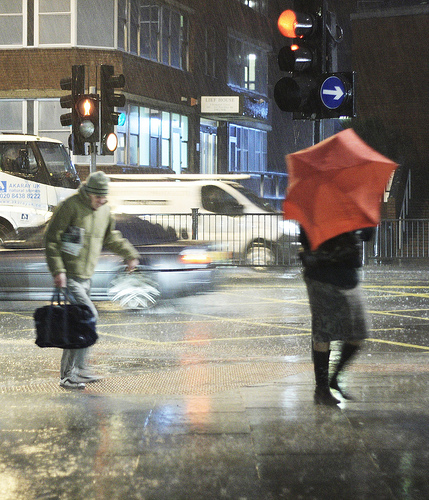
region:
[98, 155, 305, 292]
white van parked in parking lot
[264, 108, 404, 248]
red umbrella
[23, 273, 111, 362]
black canvas breif case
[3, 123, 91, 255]
cab of white truck with blue words on side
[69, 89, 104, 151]
corss walk signal light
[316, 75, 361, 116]
blue and white directional light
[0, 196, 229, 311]
black car driving down street in rain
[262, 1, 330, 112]
signal light on red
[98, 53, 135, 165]
city signal light on green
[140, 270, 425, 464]
rain on city street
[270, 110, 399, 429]
woman with red umbrella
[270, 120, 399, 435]
woman wearing black boots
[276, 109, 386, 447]
woman walking in rain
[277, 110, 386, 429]
woman wearing skirt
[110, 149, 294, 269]
white van driving in rain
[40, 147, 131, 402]
man walking in rain with no umbrella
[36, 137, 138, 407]
man wearing green jacket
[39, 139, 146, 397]
man holding black bag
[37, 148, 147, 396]
man holding newpaper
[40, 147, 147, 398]
man wearing green hat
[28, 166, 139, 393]
a person crossing a street.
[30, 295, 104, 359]
A black suit case.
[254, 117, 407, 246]
A red umbrella.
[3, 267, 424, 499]
A street soaked in rain.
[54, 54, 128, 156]
A traffic signal.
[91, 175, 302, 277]
A white van in the rain.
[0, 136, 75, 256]
A large white bus.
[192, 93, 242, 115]
A sign above a street.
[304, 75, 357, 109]
An arrow pointing right.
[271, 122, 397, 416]
A man walking with an umbrella.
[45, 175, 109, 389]
this is a man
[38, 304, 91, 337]
this is a bag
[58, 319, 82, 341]
the bag is black in color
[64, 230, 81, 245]
this is a magazine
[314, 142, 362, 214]
this is an umbrella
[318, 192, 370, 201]
the umbrella is red in color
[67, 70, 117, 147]
this is a traffic light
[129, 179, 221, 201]
this is a vehicle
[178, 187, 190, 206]
the vehicle is white in color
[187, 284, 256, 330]
this is the road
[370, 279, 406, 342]
rain drops falling on the ground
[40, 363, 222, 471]
shadow cast on the ground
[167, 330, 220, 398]
bright light on the ground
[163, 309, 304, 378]
yellow lines on the ground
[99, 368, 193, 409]
silver grates on the street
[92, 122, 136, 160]
white light on traffic light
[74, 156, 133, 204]
gray and black wool cap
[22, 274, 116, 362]
blue bag in man's hand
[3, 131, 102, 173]
window in white bus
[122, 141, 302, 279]
white van in the distance